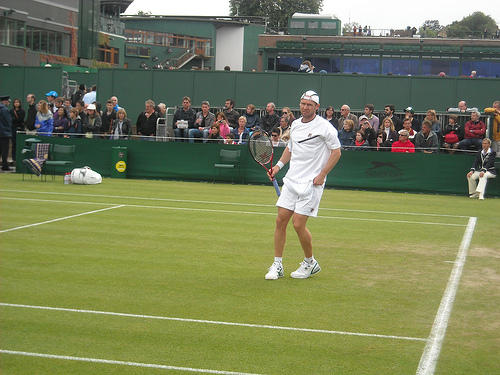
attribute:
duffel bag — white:
[66, 166, 110, 193]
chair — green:
[31, 134, 91, 188]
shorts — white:
[276, 175, 325, 220]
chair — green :
[39, 143, 71, 178]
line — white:
[107, 308, 239, 329]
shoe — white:
[263, 258, 285, 281]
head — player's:
[294, 89, 319, 119]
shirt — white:
[284, 115, 339, 184]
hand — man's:
[262, 163, 279, 179]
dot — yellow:
[113, 156, 128, 175]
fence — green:
[142, 147, 190, 172]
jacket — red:
[395, 140, 415, 148]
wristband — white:
[274, 160, 286, 168]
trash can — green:
[109, 148, 132, 181]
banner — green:
[139, 146, 208, 178]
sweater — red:
[392, 141, 412, 147]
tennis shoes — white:
[259, 254, 322, 283]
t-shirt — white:
[281, 114, 342, 194]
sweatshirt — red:
[386, 134, 416, 155]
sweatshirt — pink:
[215, 121, 233, 135]